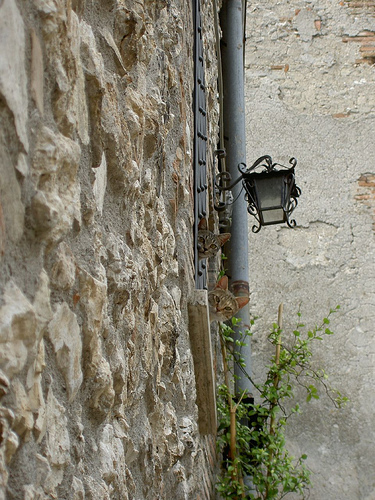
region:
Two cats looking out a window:
[188, 206, 249, 334]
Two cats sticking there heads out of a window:
[197, 203, 250, 343]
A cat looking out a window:
[194, 203, 232, 265]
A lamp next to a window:
[221, 141, 303, 234]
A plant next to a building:
[222, 303, 306, 499]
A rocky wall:
[23, 73, 187, 489]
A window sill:
[183, 279, 224, 446]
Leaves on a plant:
[229, 402, 280, 480]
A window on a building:
[191, 70, 229, 399]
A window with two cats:
[183, 71, 261, 433]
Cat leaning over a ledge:
[204, 274, 252, 326]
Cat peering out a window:
[195, 215, 236, 269]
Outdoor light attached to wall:
[213, 150, 312, 236]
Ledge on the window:
[188, 286, 221, 443]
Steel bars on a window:
[191, 6, 212, 222]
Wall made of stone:
[45, 178, 184, 436]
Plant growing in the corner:
[212, 343, 309, 499]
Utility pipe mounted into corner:
[220, 10, 262, 409]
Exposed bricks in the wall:
[337, 26, 373, 71]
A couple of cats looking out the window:
[189, 205, 255, 333]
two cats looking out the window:
[193, 206, 256, 336]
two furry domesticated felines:
[190, 208, 256, 331]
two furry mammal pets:
[187, 204, 254, 336]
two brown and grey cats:
[190, 205, 256, 335]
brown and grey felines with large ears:
[185, 202, 256, 338]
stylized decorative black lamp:
[212, 141, 307, 253]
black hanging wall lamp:
[204, 155, 318, 241]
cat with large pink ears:
[208, 263, 256, 340]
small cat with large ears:
[194, 200, 239, 267]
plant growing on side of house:
[215, 294, 324, 497]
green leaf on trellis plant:
[322, 328, 337, 337]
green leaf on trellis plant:
[231, 317, 240, 329]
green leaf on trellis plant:
[296, 453, 310, 462]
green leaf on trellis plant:
[283, 458, 294, 473]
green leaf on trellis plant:
[245, 406, 253, 415]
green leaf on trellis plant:
[289, 326, 302, 339]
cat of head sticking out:
[206, 279, 246, 324]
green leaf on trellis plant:
[210, 413, 227, 429]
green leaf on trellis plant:
[285, 324, 300, 335]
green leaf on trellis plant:
[252, 456, 263, 471]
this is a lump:
[254, 148, 290, 218]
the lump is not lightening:
[260, 180, 289, 218]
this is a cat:
[208, 275, 241, 316]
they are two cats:
[196, 219, 238, 301]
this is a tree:
[222, 369, 306, 495]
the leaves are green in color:
[245, 414, 262, 457]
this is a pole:
[226, 11, 252, 162]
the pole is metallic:
[223, 45, 248, 146]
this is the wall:
[57, 24, 125, 179]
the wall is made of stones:
[28, 410, 139, 473]